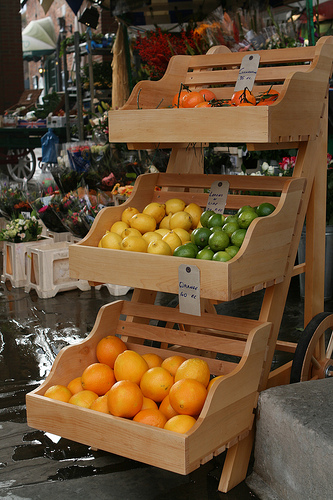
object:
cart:
[24, 34, 332, 496]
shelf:
[67, 172, 307, 304]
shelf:
[24, 298, 273, 479]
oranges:
[105, 376, 142, 418]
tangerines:
[231, 88, 257, 107]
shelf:
[108, 34, 333, 146]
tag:
[205, 178, 229, 216]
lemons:
[127, 213, 156, 235]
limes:
[206, 228, 229, 254]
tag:
[175, 264, 200, 319]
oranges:
[168, 378, 208, 414]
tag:
[233, 52, 260, 94]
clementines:
[181, 91, 207, 111]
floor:
[0, 282, 263, 499]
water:
[0, 278, 145, 479]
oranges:
[139, 365, 173, 402]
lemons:
[207, 228, 228, 253]